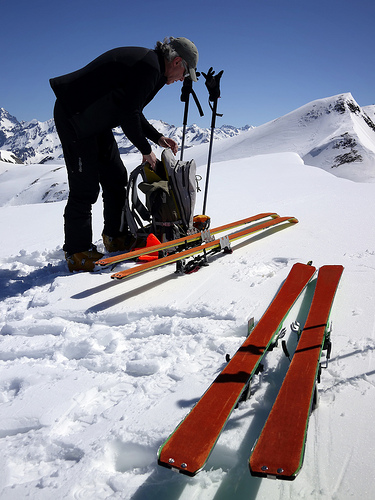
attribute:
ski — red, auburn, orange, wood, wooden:
[246, 245, 348, 484]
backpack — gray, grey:
[125, 146, 205, 248]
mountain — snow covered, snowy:
[2, 107, 261, 169]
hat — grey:
[163, 28, 204, 86]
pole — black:
[197, 61, 225, 215]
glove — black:
[198, 64, 227, 107]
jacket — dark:
[49, 39, 167, 154]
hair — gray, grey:
[160, 36, 178, 66]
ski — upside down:
[109, 214, 300, 290]